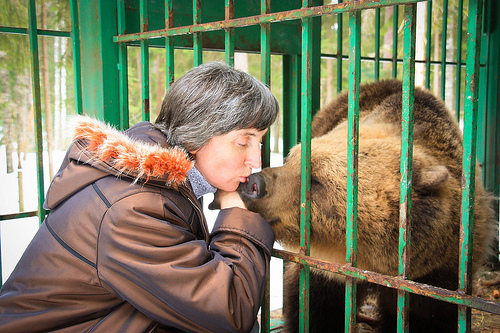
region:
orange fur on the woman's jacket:
[67, 117, 191, 183]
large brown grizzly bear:
[252, 82, 494, 328]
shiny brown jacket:
[7, 130, 272, 331]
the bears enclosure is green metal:
[3, 1, 495, 328]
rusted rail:
[281, 250, 478, 311]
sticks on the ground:
[467, 312, 498, 329]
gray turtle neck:
[187, 165, 214, 197]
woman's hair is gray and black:
[157, 62, 279, 152]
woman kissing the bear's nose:
[233, 167, 265, 197]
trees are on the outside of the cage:
[4, 0, 78, 190]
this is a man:
[50, 78, 276, 330]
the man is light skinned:
[218, 153, 242, 178]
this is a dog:
[314, 80, 431, 283]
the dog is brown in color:
[359, 161, 391, 206]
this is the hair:
[209, 83, 256, 115]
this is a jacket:
[73, 212, 150, 295]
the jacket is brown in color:
[136, 212, 173, 256]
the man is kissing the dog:
[234, 164, 256, 190]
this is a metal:
[343, 14, 369, 115]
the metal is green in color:
[340, 38, 376, 81]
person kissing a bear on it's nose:
[158, 52, 289, 232]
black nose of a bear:
[241, 171, 264, 205]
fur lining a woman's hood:
[80, 111, 189, 186]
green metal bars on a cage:
[234, 11, 477, 306]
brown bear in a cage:
[229, 53, 491, 329]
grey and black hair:
[154, 48, 271, 155]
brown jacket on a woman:
[2, 101, 262, 331]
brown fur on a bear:
[365, 181, 381, 218]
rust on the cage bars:
[338, 245, 456, 307]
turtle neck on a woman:
[178, 153, 218, 208]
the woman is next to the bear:
[143, 59, 476, 211]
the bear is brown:
[240, 70, 420, 311]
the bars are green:
[242, 33, 430, 264]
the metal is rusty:
[290, 29, 427, 180]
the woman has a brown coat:
[43, 156, 293, 327]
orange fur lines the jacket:
[81, 100, 250, 202]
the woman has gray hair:
[169, 63, 262, 101]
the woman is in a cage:
[27, 48, 419, 325]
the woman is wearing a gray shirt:
[189, 154, 234, 239]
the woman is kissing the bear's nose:
[222, 158, 306, 233]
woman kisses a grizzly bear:
[143, 45, 288, 230]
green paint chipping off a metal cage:
[278, 151, 478, 326]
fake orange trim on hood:
[71, 114, 190, 185]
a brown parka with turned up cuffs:
[0, 114, 272, 331]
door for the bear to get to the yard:
[118, 35, 302, 330]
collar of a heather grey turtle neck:
[185, 153, 221, 212]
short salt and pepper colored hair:
[154, 60, 280, 150]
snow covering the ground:
[1, 145, 58, 265]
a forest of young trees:
[3, 0, 76, 213]